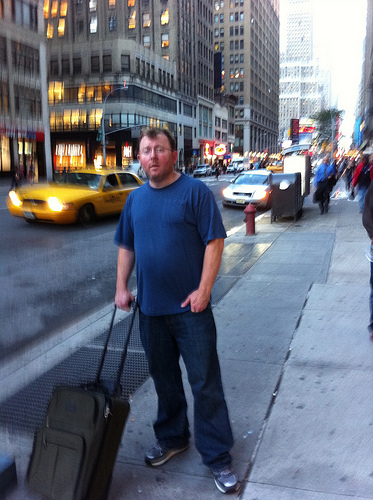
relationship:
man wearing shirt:
[298, 153, 343, 218] [315, 162, 335, 185]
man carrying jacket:
[298, 153, 343, 218] [310, 171, 339, 204]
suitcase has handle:
[23, 372, 130, 499] [95, 291, 140, 394]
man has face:
[111, 124, 239, 494] [138, 131, 173, 180]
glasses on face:
[136, 146, 171, 155] [138, 131, 173, 180]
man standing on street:
[111, 124, 239, 494] [0, 139, 243, 344]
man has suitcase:
[111, 124, 239, 494] [23, 372, 130, 499]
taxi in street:
[5, 169, 145, 225] [0, 166, 273, 361]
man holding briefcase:
[298, 153, 343, 218] [312, 189, 320, 204]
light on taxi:
[47, 196, 64, 213] [3, 165, 146, 226]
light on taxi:
[7, 190, 22, 206] [3, 165, 146, 226]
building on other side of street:
[44, 0, 218, 181] [0, 166, 273, 361]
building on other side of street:
[212, 0, 276, 159] [0, 166, 273, 361]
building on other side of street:
[275, 0, 335, 145] [0, 166, 273, 361]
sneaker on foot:
[145, 442, 189, 469] [142, 440, 187, 464]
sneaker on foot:
[207, 466, 240, 497] [210, 463, 241, 496]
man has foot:
[111, 124, 239, 494] [210, 463, 241, 496]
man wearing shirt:
[111, 124, 239, 494] [111, 174, 225, 315]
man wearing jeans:
[111, 124, 239, 494] [137, 302, 238, 472]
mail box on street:
[264, 170, 308, 229] [0, 139, 243, 344]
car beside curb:
[220, 169, 274, 211] [0, 205, 273, 371]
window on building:
[71, 53, 83, 77] [44, 0, 218, 181]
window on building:
[54, 79, 63, 102] [44, 0, 218, 181]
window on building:
[93, 148, 104, 171] [44, 0, 218, 181]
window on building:
[119, 51, 131, 76] [44, 0, 218, 181]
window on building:
[158, 7, 169, 27] [44, 0, 218, 181]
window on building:
[141, 12, 151, 30] [44, 0, 218, 181]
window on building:
[106, 12, 118, 33] [44, 0, 218, 181]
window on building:
[55, 20, 67, 36] [44, 0, 218, 181]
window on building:
[160, 34, 170, 47] [44, 0, 218, 181]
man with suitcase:
[111, 124, 239, 494] [22, 290, 137, 496]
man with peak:
[111, 124, 239, 494] [145, 129, 167, 139]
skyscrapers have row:
[2, 2, 334, 176] [2, 2, 333, 169]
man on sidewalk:
[298, 153, 343, 218] [210, 166, 357, 427]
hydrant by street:
[242, 200, 258, 237] [0, 139, 243, 344]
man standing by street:
[111, 124, 239, 494] [0, 139, 243, 344]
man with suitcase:
[111, 124, 239, 494] [15, 373, 126, 493]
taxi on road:
[5, 169, 145, 225] [18, 256, 66, 302]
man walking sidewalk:
[298, 153, 343, 218] [325, 218, 360, 382]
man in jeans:
[111, 124, 239, 494] [129, 300, 245, 466]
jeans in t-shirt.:
[129, 300, 245, 466] [116, 170, 235, 315]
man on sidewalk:
[298, 153, 343, 218] [295, 318, 360, 470]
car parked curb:
[220, 169, 274, 211] [239, 198, 267, 236]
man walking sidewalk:
[335, 164, 360, 239] [302, 207, 348, 497]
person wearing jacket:
[348, 158, 360, 201] [348, 150, 359, 187]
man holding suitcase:
[111, 124, 239, 494] [16, 297, 136, 490]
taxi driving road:
[5, 169, 145, 225] [25, 239, 74, 271]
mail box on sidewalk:
[264, 170, 308, 229] [312, 209, 344, 464]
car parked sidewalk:
[220, 169, 274, 211] [331, 217, 349, 495]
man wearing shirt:
[298, 153, 343, 218] [312, 163, 336, 192]